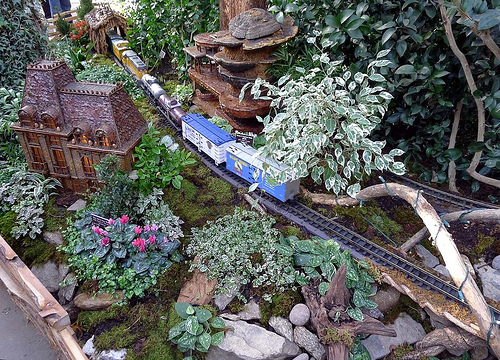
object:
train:
[106, 29, 306, 205]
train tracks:
[103, 34, 498, 319]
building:
[8, 58, 151, 191]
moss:
[161, 173, 238, 228]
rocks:
[287, 300, 312, 327]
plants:
[131, 124, 196, 193]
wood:
[183, 0, 299, 121]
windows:
[93, 131, 111, 150]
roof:
[19, 57, 143, 140]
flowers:
[146, 232, 160, 248]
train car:
[221, 141, 305, 202]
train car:
[180, 112, 233, 170]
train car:
[120, 50, 146, 80]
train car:
[111, 38, 127, 62]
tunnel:
[83, 5, 141, 54]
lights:
[374, 174, 390, 186]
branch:
[296, 175, 499, 355]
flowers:
[68, 19, 88, 42]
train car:
[157, 95, 185, 125]